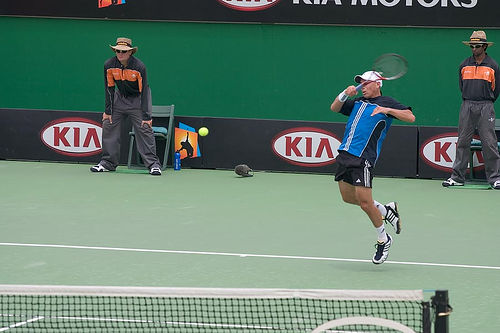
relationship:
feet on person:
[371, 232, 393, 264] [334, 61, 414, 268]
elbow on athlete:
[405, 109, 416, 123] [322, 38, 420, 283]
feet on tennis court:
[371, 232, 393, 264] [2, 159, 499, 330]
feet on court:
[364, 201, 404, 266] [0, 158, 499, 331]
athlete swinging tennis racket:
[329, 71, 416, 265] [340, 53, 409, 98]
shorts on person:
[328, 146, 408, 214] [308, 79, 452, 221]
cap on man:
[352, 67, 384, 93] [337, 58, 406, 259]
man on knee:
[90, 34, 163, 175] [137, 119, 155, 132]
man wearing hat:
[441, 29, 498, 189] [461, 29, 491, 46]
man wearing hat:
[90, 34, 163, 175] [107, 37, 138, 50]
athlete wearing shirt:
[329, 71, 416, 265] [341, 94, 411, 165]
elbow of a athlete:
[396, 104, 418, 141] [329, 71, 416, 265]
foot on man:
[486, 177, 498, 188] [441, 29, 498, 189]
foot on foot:
[486, 177, 498, 188] [440, 178, 461, 191]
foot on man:
[146, 161, 162, 174] [90, 34, 163, 175]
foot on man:
[88, 159, 107, 175] [90, 34, 163, 175]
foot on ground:
[486, 177, 498, 188] [0, 159, 499, 330]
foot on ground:
[440, 178, 461, 191] [0, 159, 499, 330]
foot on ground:
[146, 161, 162, 174] [0, 159, 499, 330]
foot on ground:
[88, 159, 107, 175] [0, 159, 499, 330]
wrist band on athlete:
[338, 92, 347, 102] [329, 71, 416, 265]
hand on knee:
[99, 110, 112, 122] [132, 122, 153, 142]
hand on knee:
[102, 112, 113, 124] [102, 118, 121, 141]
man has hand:
[90, 34, 163, 175] [99, 110, 112, 122]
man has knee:
[90, 34, 163, 175] [132, 122, 153, 142]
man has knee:
[90, 34, 163, 175] [102, 118, 121, 141]